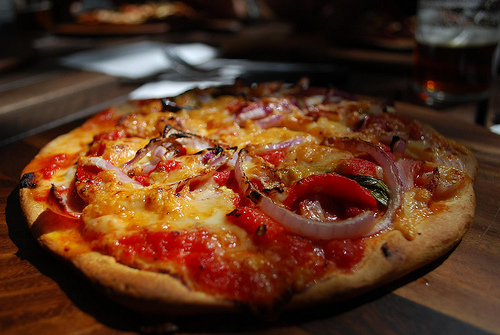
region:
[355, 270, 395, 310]
edge of a pizza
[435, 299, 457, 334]
part of a shade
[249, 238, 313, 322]
part of a pizza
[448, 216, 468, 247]
part of a pizza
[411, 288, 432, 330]
part of a shade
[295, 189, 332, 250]
part of an onion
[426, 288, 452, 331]
aprt of a table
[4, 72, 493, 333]
pizza on wood surface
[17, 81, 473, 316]
round pizza on surface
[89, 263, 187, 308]
brown crust on pizza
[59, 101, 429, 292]
toppings on pizza surface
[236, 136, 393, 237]
round slice of onion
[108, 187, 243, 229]
melted cheese of pizza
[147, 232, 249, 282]
red of tomato sauce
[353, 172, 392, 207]
piece of green vegetable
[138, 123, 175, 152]
burnt edge of onion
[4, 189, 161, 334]
shadow on side of pizza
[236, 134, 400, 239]
A large onion on this side of the pizza.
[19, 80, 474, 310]
A small burnt crust pizza with onions.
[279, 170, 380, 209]
A red piece of pepperoni sticking up in an onion.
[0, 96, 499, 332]
A brown wood table a pizza is on.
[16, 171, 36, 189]
A dark big black spot on a pizza.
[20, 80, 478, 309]
A small pizza on a table.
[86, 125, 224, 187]
A half burnt at the top onion on the left.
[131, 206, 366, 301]
Red saucy crust area.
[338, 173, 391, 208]
A green piece of leaf on a pizza.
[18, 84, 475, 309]
A small round pepperoni and onion pizza.